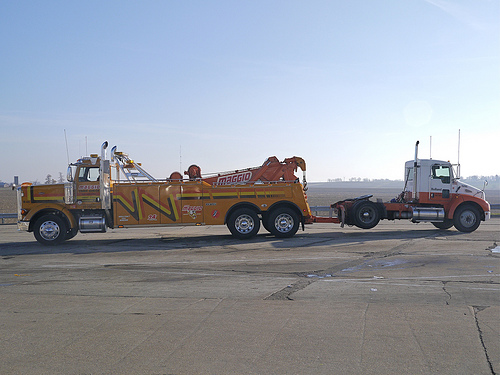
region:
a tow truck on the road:
[8, 77, 499, 318]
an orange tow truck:
[23, 100, 358, 257]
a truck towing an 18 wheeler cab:
[12, 74, 496, 291]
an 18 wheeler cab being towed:
[15, 43, 485, 300]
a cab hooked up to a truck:
[15, 70, 499, 232]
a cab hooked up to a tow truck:
[7, 87, 490, 277]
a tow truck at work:
[24, 82, 477, 309]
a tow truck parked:
[2, 90, 497, 318]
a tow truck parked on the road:
[11, 63, 498, 281]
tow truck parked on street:
[5, 72, 493, 353]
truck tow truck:
[43, 155, 311, 240]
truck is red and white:
[378, 155, 486, 232]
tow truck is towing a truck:
[252, 141, 493, 258]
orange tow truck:
[31, 176, 324, 235]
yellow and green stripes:
[99, 174, 321, 223]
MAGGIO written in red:
[197, 164, 263, 187]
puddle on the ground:
[320, 238, 426, 299]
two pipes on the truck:
[98, 129, 127, 171]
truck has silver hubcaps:
[32, 218, 69, 251]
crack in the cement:
[446, 291, 495, 371]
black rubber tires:
[222, 197, 309, 254]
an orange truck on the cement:
[13, 119, 335, 281]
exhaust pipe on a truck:
[407, 125, 420, 187]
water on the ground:
[339, 233, 412, 290]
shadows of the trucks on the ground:
[22, 196, 319, 281]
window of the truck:
[424, 160, 460, 177]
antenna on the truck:
[60, 123, 71, 196]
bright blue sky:
[111, 17, 246, 99]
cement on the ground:
[125, 280, 217, 363]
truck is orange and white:
[385, 140, 497, 237]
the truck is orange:
[5, 92, 312, 259]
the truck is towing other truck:
[25, 84, 497, 315]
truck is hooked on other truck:
[322, 110, 494, 257]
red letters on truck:
[208, 163, 262, 198]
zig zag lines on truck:
[107, 184, 199, 224]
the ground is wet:
[285, 237, 427, 312]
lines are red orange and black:
[9, 175, 314, 221]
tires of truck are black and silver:
[19, 201, 329, 253]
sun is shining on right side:
[415, 2, 495, 184]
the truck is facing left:
[19, 144, 314, 241]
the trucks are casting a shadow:
[2, 222, 484, 251]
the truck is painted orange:
[17, 166, 309, 236]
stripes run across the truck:
[33, 191, 283, 224]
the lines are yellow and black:
[27, 188, 294, 225]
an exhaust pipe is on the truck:
[97, 141, 109, 203]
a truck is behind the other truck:
[340, 153, 489, 233]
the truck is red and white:
[346, 156, 489, 234]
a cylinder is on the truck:
[77, 213, 108, 233]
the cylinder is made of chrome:
[76, 215, 107, 233]